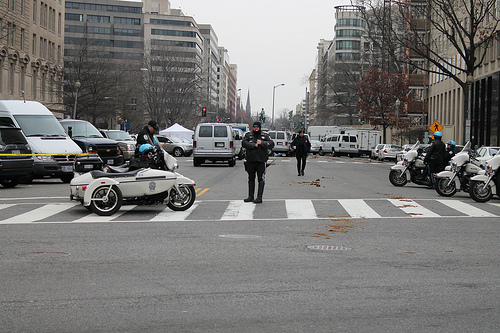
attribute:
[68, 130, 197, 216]
motorcycle — white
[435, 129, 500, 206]
motorcycle — white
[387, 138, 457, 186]
motorcycle — white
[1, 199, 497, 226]
crosswalk — white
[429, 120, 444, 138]
sign — walking figure, black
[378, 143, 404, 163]
car — white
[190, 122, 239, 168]
van — white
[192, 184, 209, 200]
lines — yellow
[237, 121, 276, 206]
officer — standing, law, patrolling, beginning, finished, armed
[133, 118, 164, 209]
officer — standing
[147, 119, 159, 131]
hat — black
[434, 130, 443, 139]
helmet — blue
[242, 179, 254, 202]
boots — black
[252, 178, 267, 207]
boots — black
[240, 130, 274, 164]
jacket — black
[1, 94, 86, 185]
van — parked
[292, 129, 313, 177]
man — walking, standing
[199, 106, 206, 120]
light — red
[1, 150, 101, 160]
tape — yellow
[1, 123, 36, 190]
car — black